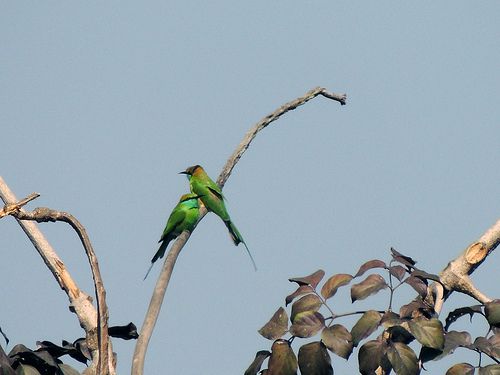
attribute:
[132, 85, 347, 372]
branch — top  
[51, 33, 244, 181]
clouds — white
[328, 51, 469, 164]
sky — blue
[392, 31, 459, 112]
clouds — white 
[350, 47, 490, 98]
sky — blue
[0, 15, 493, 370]
sky — blue ,  blue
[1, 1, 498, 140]
sky — blue 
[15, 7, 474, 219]
sky — blue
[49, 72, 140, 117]
clouds — white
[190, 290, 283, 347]
clouds —  white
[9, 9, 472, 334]
sky — blue ,  blue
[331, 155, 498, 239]
clouds — white 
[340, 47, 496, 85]
sky — blue 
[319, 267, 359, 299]
leaf — one 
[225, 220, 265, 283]
feather — tail 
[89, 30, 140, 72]
clouds — white 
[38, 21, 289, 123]
clouds — white  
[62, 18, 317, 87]
sky — white, blue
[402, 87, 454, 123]
clouds —  white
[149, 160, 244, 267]
birds — green  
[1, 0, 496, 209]
sky — blue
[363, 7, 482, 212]
sky — clear blue 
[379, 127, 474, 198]
sky — blue 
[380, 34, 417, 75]
clouds —  white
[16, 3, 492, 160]
sky —  blue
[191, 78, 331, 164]
clouds — white 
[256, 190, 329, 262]
clouds — white 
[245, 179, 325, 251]
clouds — white 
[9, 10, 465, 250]
sky — blue 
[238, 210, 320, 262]
clouds — white 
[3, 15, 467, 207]
sky — blue  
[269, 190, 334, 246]
clouds — white  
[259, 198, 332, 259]
clouds — white 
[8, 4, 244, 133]
clouds — white